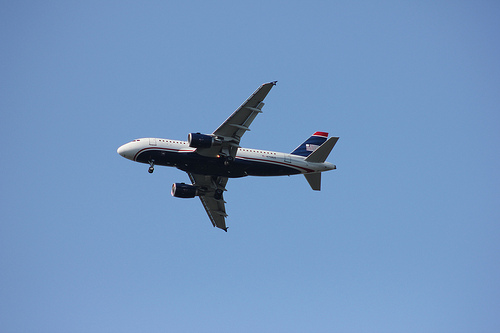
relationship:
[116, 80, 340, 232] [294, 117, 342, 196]
flight has tail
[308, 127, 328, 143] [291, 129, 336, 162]
red trim on tail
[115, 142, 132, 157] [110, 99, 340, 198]
nose of a jet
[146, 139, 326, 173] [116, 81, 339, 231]
fuselage on a jet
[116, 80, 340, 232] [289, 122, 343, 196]
flight has tail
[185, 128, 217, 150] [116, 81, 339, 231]
engine powering jet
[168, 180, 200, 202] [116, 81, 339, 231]
engine powering jet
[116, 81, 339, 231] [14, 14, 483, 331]
jet flying through sky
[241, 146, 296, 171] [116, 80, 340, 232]
windows on flight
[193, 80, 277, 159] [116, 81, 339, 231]
wing on jet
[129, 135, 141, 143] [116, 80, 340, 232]
windows on flight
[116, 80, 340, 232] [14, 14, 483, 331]
flight in sky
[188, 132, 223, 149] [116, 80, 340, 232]
engine on flight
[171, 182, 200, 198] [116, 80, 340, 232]
engine on flight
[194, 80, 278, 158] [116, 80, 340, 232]
wing on flight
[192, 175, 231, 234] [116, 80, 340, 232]
wing on flight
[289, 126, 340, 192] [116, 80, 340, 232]
tail on flight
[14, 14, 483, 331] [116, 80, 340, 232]
sky above flight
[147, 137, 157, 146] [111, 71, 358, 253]
door on plane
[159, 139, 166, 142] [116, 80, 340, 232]
window on flight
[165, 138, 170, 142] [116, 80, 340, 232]
window on flight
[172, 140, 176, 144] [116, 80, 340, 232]
window on flight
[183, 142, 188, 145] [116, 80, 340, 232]
window on flight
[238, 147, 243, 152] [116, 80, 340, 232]
window on flight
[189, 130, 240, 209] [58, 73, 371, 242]
wheels under plane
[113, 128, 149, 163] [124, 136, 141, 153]
pit of jet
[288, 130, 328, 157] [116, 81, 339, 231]
tail fin of jet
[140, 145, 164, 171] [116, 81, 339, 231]
landing gear of jet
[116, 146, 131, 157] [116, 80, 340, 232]
nose of flight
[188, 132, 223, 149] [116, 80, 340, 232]
engine of flight